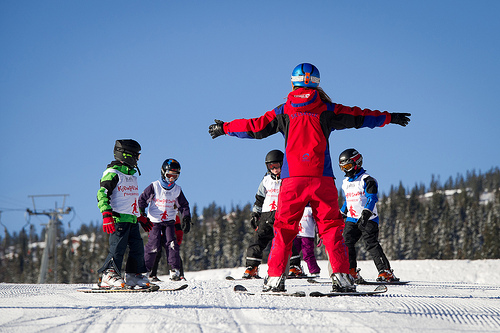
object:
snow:
[17, 262, 495, 329]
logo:
[117, 185, 138, 197]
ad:
[137, 114, 398, 296]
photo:
[8, 8, 499, 331]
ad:
[74, 4, 499, 52]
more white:
[421, 261, 451, 278]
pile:
[1, 270, 498, 331]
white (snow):
[1, 260, 498, 328]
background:
[6, 10, 496, 264]